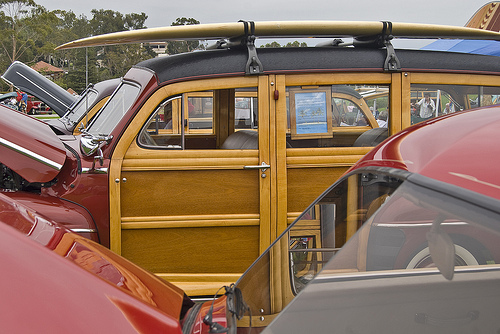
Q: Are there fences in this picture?
A: No, there are no fences.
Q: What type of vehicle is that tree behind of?
A: The tree is behind the car.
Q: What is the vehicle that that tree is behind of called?
A: The vehicle is a car.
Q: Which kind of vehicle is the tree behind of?
A: The tree is behind the car.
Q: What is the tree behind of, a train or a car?
A: The tree is behind a car.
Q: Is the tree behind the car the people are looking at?
A: Yes, the tree is behind the car.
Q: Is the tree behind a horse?
A: No, the tree is behind the car.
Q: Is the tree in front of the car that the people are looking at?
A: No, the tree is behind the car.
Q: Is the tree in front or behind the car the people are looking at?
A: The tree is behind the car.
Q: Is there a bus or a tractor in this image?
A: No, there are no buses or tractors.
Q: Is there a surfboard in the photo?
A: Yes, there is a surfboard.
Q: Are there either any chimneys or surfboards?
A: Yes, there is a surfboard.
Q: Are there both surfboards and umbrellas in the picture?
A: No, there is a surfboard but no umbrellas.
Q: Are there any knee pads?
A: No, there are no knee pads.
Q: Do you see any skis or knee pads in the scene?
A: No, there are no knee pads or skis.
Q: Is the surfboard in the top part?
A: Yes, the surfboard is in the top of the image.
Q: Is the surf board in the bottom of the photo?
A: No, the surf board is in the top of the image.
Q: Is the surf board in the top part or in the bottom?
A: The surf board is in the top of the image.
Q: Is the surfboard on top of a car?
A: Yes, the surfboard is on top of a car.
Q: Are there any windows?
A: Yes, there is a window.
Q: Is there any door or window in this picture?
A: Yes, there is a window.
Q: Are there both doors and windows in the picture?
A: Yes, there are both a window and a door.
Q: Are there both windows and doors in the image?
A: Yes, there are both a window and a door.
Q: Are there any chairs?
A: No, there are no chairs.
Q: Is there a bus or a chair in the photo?
A: No, there are no chairs or buses.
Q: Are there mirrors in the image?
A: Yes, there is a mirror.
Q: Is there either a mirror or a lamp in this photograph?
A: Yes, there is a mirror.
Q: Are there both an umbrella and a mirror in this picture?
A: No, there is a mirror but no umbrellas.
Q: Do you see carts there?
A: No, there are no carts.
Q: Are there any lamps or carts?
A: No, there are no carts or lamps.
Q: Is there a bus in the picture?
A: No, there are no buses.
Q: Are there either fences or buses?
A: No, there are no buses or fences.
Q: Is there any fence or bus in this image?
A: No, there are no buses or fences.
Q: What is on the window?
A: The sign is on the window.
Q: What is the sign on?
A: The sign is on the window.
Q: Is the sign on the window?
A: Yes, the sign is on the window.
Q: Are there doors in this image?
A: Yes, there are doors.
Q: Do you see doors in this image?
A: Yes, there are doors.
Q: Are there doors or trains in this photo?
A: Yes, there are doors.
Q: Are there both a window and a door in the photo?
A: Yes, there are both a door and a window.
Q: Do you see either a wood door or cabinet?
A: Yes, there are wood doors.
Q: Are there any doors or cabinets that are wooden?
A: Yes, the doors are wooden.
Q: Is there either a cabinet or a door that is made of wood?
A: Yes, the doors are made of wood.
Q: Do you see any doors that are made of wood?
A: Yes, there are doors that are made of wood.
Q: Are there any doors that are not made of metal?
A: Yes, there are doors that are made of wood.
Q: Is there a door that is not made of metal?
A: Yes, there are doors that are made of wood.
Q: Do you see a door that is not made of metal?
A: Yes, there are doors that are made of wood.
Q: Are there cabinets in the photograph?
A: No, there are no cabinets.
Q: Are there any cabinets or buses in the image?
A: No, there are no cabinets or buses.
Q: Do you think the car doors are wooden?
A: Yes, the doors are wooden.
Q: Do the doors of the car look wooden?
A: Yes, the doors are wooden.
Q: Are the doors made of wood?
A: Yes, the doors are made of wood.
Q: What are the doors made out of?
A: The doors are made of wood.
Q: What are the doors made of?
A: The doors are made of wood.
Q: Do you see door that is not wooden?
A: No, there are doors but they are wooden.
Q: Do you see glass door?
A: No, there are doors but they are made of wood.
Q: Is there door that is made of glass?
A: No, there are doors but they are made of wood.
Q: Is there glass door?
A: No, there are doors but they are made of wood.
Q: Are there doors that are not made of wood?
A: No, there are doors but they are made of wood.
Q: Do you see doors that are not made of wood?
A: No, there are doors but they are made of wood.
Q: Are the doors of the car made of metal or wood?
A: The doors are made of wood.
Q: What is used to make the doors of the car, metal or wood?
A: The doors are made of wood.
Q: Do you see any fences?
A: No, there are no fences.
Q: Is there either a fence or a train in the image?
A: No, there are no fences or trains.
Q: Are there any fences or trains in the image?
A: No, there are no fences or trains.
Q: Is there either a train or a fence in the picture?
A: No, there are no fences or trains.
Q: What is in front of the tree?
A: The car is in front of the tree.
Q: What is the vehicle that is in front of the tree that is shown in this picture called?
A: The vehicle is a car.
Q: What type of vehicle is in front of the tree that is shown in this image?
A: The vehicle is a car.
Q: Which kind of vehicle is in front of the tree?
A: The vehicle is a car.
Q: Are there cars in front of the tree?
A: Yes, there is a car in front of the tree.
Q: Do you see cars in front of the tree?
A: Yes, there is a car in front of the tree.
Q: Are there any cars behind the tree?
A: No, the car is in front of the tree.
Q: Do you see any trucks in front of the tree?
A: No, there is a car in front of the tree.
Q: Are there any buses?
A: No, there are no buses.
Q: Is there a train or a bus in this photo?
A: No, there are no buses or trains.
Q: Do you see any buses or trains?
A: No, there are no buses or trains.